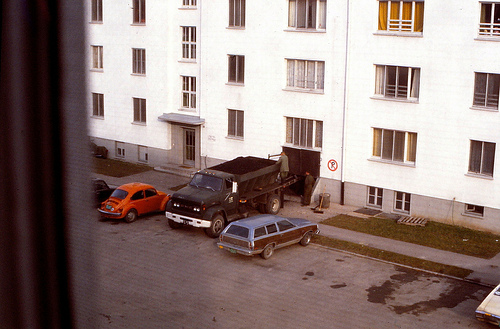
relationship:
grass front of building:
[328, 213, 499, 257] [84, 0, 498, 230]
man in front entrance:
[299, 169, 318, 207] [282, 145, 324, 198]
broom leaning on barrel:
[311, 192, 326, 216] [319, 191, 334, 211]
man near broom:
[299, 169, 318, 207] [311, 192, 326, 216]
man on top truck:
[276, 148, 291, 180] [157, 151, 299, 221]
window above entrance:
[281, 109, 326, 151] [282, 145, 324, 198]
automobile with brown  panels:
[214, 206, 323, 261] [248, 223, 321, 249]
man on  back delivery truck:
[299, 169, 318, 207] [157, 151, 299, 221]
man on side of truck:
[299, 169, 318, 207] [157, 151, 299, 221]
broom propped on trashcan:
[311, 192, 326, 216] [319, 191, 334, 211]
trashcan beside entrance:
[319, 191, 334, 211] [282, 145, 324, 198]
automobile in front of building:
[214, 206, 323, 261] [84, 0, 498, 230]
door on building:
[282, 145, 324, 198] [84, 0, 498, 230]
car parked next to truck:
[96, 176, 174, 228] [157, 151, 299, 221]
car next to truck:
[96, 176, 174, 228] [157, 151, 299, 221]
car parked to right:
[214, 206, 323, 261] [468, 4, 498, 327]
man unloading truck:
[299, 169, 314, 207] [157, 151, 299, 221]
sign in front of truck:
[325, 158, 337, 170] [164, 156, 299, 238]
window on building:
[282, 58, 325, 93] [84, 0, 498, 230]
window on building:
[368, 63, 424, 104] [84, 0, 498, 230]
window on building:
[223, 52, 248, 86] [84, 0, 498, 230]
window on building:
[365, 124, 420, 166] [84, 0, 498, 230]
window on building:
[225, 106, 248, 142] [84, 0, 498, 230]